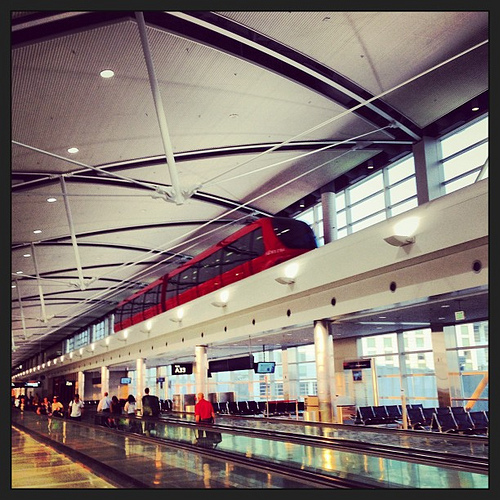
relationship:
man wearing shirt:
[195, 391, 216, 438] [193, 400, 212, 420]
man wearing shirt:
[195, 391, 216, 438] [173, 382, 221, 422]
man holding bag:
[195, 391, 216, 438] [189, 428, 213, 449]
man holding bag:
[195, 391, 216, 438] [209, 423, 223, 442]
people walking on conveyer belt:
[41, 390, 161, 434] [115, 410, 231, 452]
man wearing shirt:
[187, 390, 217, 422] [189, 395, 216, 420]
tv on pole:
[350, 370, 366, 383] [369, 358, 381, 405]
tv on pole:
[121, 370, 132, 385] [96, 364, 112, 408]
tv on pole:
[255, 359, 275, 373] [312, 319, 339, 429]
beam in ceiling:
[13, 12, 489, 203] [11, 11, 486, 365]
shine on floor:
[284, 435, 433, 487] [9, 405, 489, 491]